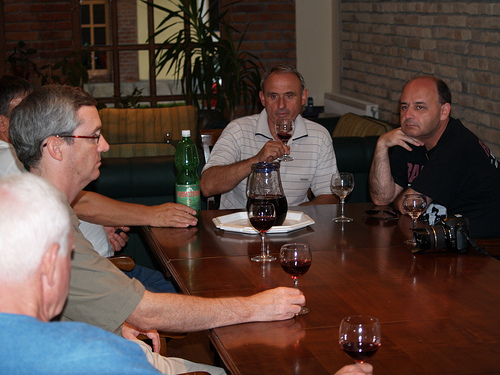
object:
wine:
[271, 107, 296, 162]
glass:
[246, 196, 284, 265]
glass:
[331, 172, 357, 227]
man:
[6, 81, 308, 329]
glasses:
[39, 127, 105, 149]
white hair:
[0, 170, 61, 284]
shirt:
[220, 104, 357, 215]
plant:
[140, 0, 271, 124]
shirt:
[390, 124, 499, 241]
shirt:
[0, 304, 160, 373]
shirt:
[66, 207, 122, 264]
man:
[0, 167, 215, 375]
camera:
[409, 209, 486, 256]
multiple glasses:
[238, 162, 473, 365]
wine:
[343, 340, 379, 361]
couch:
[83, 102, 202, 194]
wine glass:
[331, 170, 356, 224]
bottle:
[171, 127, 206, 223]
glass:
[280, 244, 312, 316]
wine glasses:
[246, 194, 285, 262]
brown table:
[136, 188, 499, 370]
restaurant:
[6, 2, 496, 372]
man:
[202, 65, 347, 207]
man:
[367, 70, 497, 255]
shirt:
[19, 168, 145, 337]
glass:
[334, 310, 383, 363]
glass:
[400, 191, 424, 245]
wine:
[246, 214, 276, 230]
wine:
[277, 256, 311, 275]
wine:
[401, 203, 426, 218]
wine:
[330, 181, 355, 200]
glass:
[273, 114, 294, 162]